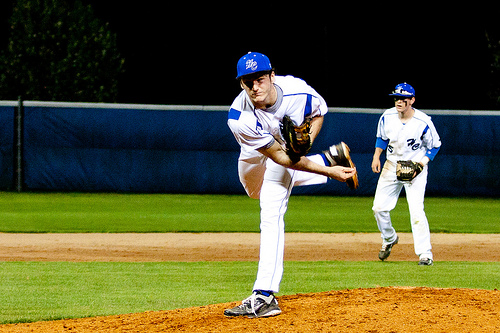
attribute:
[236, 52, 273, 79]
cap — blue, baseball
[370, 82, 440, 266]
player — baseball player, an outfielder, focused, awaiting hit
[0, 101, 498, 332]
field — baseball field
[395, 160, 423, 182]
mit — baseball glove, brown, black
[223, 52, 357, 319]
player — a  pitcher, pitching, baseball player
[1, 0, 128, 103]
tree — dark green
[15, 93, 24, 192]
post — metal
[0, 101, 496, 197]
fence — covered, padded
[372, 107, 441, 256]
uniform — blue, white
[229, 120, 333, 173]
arm — slant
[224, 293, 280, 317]
sneaker — nike, grey, black, white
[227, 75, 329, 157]
jersey — blue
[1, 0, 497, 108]
sky — dark